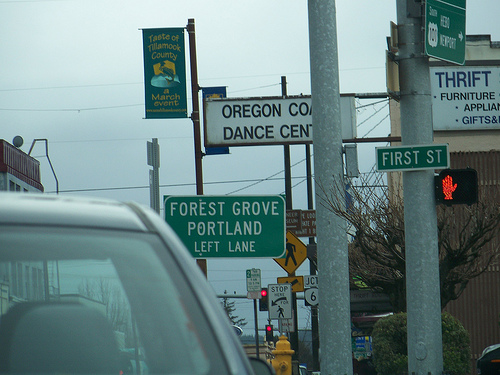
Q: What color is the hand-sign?
A: Red.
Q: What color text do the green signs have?
A: White.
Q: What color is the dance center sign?
A: White.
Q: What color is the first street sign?
A: Green.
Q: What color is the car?
A: Black.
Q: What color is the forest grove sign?
A: Green.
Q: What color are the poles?
A: Gray.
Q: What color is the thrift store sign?
A: White.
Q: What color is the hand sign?
A: Red.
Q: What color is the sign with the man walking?
A: Yellow.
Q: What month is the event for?
A: March.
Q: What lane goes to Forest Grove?
A: Left lane.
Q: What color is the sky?
A: White.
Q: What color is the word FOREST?
A: White.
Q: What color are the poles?
A: Gray.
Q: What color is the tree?
A: Brown.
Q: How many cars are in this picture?
A: One.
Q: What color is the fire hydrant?
A: Yellow.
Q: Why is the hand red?
A: Not safe to cross.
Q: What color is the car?
A: Silver.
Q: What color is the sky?
A: Grey.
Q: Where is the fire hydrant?
A: Behind the car.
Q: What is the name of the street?
A: First St.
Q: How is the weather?
A: Cloudy.